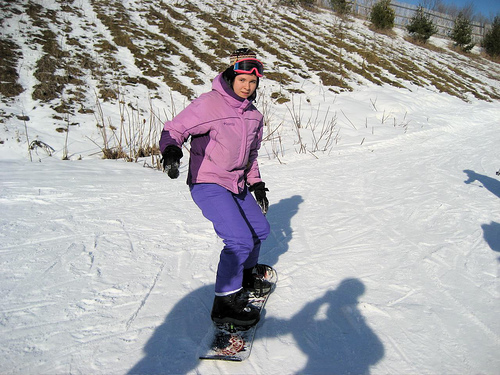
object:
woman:
[158, 47, 272, 327]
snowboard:
[198, 263, 278, 362]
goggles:
[232, 59, 264, 77]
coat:
[158, 73, 265, 195]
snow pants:
[188, 183, 271, 296]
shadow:
[289, 277, 385, 375]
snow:
[0, 161, 499, 374]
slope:
[0, 0, 499, 158]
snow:
[0, 0, 499, 133]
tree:
[449, 11, 477, 53]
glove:
[160, 144, 183, 179]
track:
[1, 118, 500, 373]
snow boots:
[211, 268, 272, 328]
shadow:
[257, 194, 303, 265]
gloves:
[248, 181, 269, 215]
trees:
[296, 0, 499, 61]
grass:
[0, 0, 499, 162]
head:
[230, 65, 260, 99]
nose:
[244, 81, 251, 90]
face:
[233, 74, 258, 99]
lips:
[241, 92, 249, 95]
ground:
[2, 0, 500, 374]